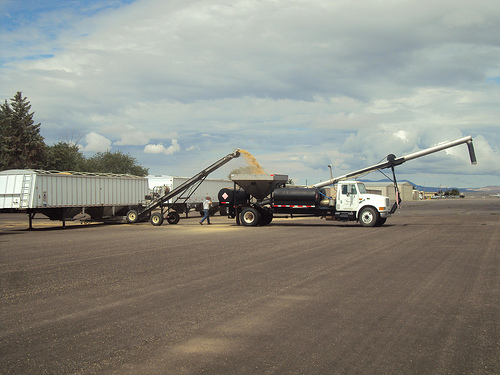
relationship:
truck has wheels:
[228, 171, 395, 227] [359, 204, 380, 227]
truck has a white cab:
[228, 171, 395, 227] [337, 180, 391, 226]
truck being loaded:
[228, 171, 395, 227] [237, 148, 394, 226]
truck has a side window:
[228, 171, 395, 227] [341, 185, 356, 195]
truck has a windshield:
[228, 171, 395, 227] [356, 180, 368, 195]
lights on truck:
[378, 205, 388, 213] [228, 171, 395, 227]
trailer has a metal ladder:
[0, 169, 149, 231] [19, 171, 34, 210]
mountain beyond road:
[390, 178, 499, 197] [405, 201, 500, 373]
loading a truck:
[230, 147, 391, 228] [228, 171, 395, 227]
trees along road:
[0, 92, 149, 175] [0, 231, 499, 374]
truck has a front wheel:
[228, 171, 395, 227] [359, 204, 380, 227]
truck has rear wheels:
[228, 171, 395, 227] [240, 205, 259, 228]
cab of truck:
[337, 180, 391, 226] [228, 171, 395, 227]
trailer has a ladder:
[0, 169, 149, 231] [19, 171, 34, 210]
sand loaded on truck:
[237, 148, 265, 178] [228, 171, 395, 227]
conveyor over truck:
[126, 147, 240, 226] [228, 171, 395, 227]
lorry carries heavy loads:
[228, 171, 395, 227] [237, 148, 394, 226]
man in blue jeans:
[199, 194, 214, 226] [199, 209, 213, 226]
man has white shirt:
[199, 194, 214, 226] [203, 197, 213, 210]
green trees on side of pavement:
[0, 92, 149, 175] [0, 231, 499, 374]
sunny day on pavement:
[1, 1, 499, 375] [0, 231, 499, 374]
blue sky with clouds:
[1, 3, 496, 84] [41, 1, 499, 135]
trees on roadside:
[0, 92, 149, 175] [0, 231, 499, 374]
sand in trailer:
[237, 148, 265, 178] [0, 169, 149, 231]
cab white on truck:
[337, 180, 391, 226] [228, 171, 395, 227]